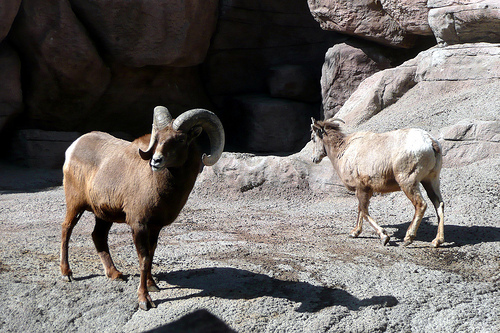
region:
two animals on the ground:
[76, 87, 438, 237]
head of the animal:
[125, 105, 237, 179]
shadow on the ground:
[223, 250, 337, 322]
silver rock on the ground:
[214, 205, 309, 257]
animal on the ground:
[276, 100, 462, 257]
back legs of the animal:
[26, 220, 126, 292]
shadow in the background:
[188, 15, 272, 78]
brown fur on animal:
[25, 87, 257, 260]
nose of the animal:
[141, 148, 171, 176]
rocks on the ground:
[206, 202, 313, 259]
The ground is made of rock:
[227, 259, 435, 320]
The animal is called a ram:
[45, 101, 233, 316]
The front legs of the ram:
[130, 240, 168, 315]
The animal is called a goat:
[298, 101, 462, 248]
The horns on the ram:
[138, 94, 228, 170]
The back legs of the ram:
[51, 211, 127, 289]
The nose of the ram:
[147, 150, 167, 165]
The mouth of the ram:
[149, 161, 164, 173]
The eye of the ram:
[168, 130, 188, 147]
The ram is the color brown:
[53, 114, 220, 291]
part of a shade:
[283, 285, 298, 298]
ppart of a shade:
[258, 266, 296, 329]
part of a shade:
[317, 284, 348, 315]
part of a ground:
[421, 275, 458, 328]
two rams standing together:
[50, 80, 445, 310]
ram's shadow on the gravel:
[134, 251, 388, 315]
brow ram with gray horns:
[53, 90, 221, 304]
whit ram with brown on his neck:
[298, 108, 460, 248]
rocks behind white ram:
[308, 38, 499, 164]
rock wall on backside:
[0, 3, 487, 145]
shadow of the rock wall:
[7, 138, 59, 198]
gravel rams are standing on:
[7, 149, 483, 332]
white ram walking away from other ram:
[294, 104, 459, 249]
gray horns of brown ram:
[118, 98, 230, 175]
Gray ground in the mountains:
[256, 238, 278, 254]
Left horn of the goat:
[197, 112, 225, 166]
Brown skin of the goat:
[102, 170, 130, 192]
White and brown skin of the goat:
[362, 143, 384, 159]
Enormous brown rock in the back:
[119, 7, 196, 52]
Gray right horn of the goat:
[153, 106, 173, 128]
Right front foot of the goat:
[133, 271, 158, 317]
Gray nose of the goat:
[150, 155, 165, 163]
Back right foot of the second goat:
[433, 207, 449, 247]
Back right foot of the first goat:
[56, 253, 78, 277]